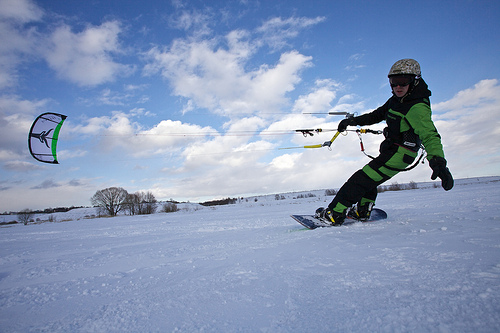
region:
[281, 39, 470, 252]
A person with snowboard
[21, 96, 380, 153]
The snowboarder was fixed to the aircraft via metal handle with rope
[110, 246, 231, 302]
White color snow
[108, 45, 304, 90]
A blue color sky with clouds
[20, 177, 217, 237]
Lot of trees with branches in the snow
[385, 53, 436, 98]
A person wearing helmet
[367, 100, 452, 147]
A person wearing black and green color jacket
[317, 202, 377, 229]
Pair of shoes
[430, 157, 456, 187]
A person wearing glove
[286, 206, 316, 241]
Snowboard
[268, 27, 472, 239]
A person in the foreground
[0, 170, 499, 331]
Snow is covering the ground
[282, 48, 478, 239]
Person in the foreground is snowboarding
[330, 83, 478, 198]
Person is wearing black gloves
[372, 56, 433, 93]
Person is wearing a light brown colored helmet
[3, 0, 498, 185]
Clouds are in the sky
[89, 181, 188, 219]
Tree in the background is bare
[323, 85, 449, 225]
Snowboarder is wearing a green and black outfit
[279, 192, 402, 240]
Snowboard has snow covering it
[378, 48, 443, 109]
Person is wearing goggles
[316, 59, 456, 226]
A person in a green and black suit with black goggles.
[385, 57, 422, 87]
Spotted helmet on a person in a green and black suit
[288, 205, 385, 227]
A dark colored snowboard.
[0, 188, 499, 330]
White snow all over the ground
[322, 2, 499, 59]
Open blue clear sky above the snowboarders head.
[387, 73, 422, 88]
Black goggles on the face of a person snowboarding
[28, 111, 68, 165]
Black and green parasail in the air.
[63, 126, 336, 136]
Two clear thin black strings going from the person to the sail.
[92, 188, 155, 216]
Majority of big leafless trees to the right of the sail.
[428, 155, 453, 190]
Black glove on the left hand of a snowboarder.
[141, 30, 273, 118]
clouds in the sky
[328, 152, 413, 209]
legs of the person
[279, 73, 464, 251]
green and black outfit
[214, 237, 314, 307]
snow under the person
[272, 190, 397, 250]
snowboard on the ground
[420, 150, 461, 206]
hand of the person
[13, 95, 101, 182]
object in the air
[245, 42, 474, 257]
person holding onto something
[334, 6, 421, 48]
blue sky above land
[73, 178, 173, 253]
trees in the distance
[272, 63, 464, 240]
a person riding a snowboard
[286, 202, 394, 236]
a black snowboard on the ground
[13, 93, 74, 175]
a green and black windsail in midair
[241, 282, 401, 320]
white snow on the ground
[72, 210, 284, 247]
a set of tracks in the snow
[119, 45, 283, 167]
cloudy white skies over the scene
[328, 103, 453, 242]
the person's green and black snowsuit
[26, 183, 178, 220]
leafless trees growing in the distance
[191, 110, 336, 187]
fluffy white clouds in the sky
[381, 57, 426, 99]
the person's camouflage helmet and black goggles